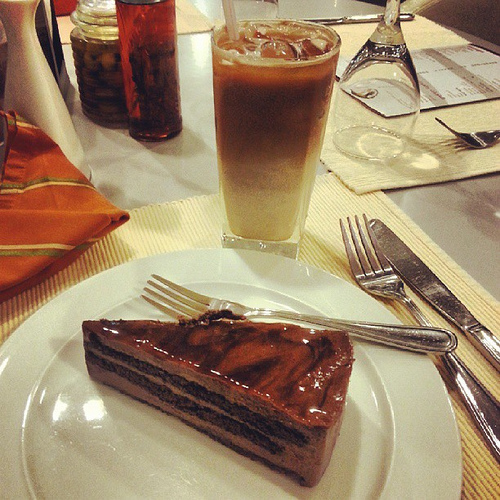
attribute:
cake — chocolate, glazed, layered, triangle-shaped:
[81, 319, 354, 490]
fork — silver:
[336, 210, 500, 465]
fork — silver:
[433, 114, 500, 151]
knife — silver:
[369, 217, 499, 372]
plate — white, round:
[1, 249, 463, 500]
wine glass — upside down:
[333, 0, 423, 166]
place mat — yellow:
[1, 171, 500, 498]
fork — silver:
[142, 271, 460, 357]